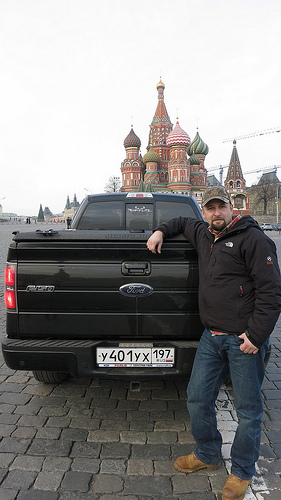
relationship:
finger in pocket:
[239, 333, 244, 338] [230, 333, 259, 357]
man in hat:
[144, 183, 278, 498] [198, 182, 233, 206]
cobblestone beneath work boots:
[56, 469, 220, 491] [170, 453, 256, 499]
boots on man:
[171, 448, 249, 496] [144, 183, 278, 498]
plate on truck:
[97, 347, 174, 367] [2, 193, 208, 363]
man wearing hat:
[144, 183, 278, 498] [198, 182, 233, 206]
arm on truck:
[162, 216, 204, 236] [1, 193, 270, 385]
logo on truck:
[119, 283, 152, 298] [1, 193, 270, 385]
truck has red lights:
[21, 178, 212, 360] [3, 255, 12, 305]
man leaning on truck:
[200, 204, 257, 457] [16, 199, 204, 374]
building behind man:
[120, 74, 251, 216] [144, 183, 278, 498]